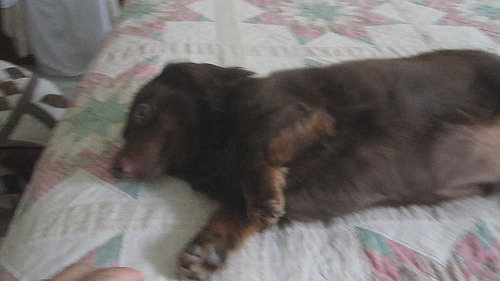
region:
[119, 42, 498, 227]
dog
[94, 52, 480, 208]
brown dog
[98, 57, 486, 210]
brown dog lying on side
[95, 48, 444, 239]
brown dog lying on side on bed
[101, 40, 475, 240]
brown dog lying on bed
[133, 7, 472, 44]
multi colored bed spread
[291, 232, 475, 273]
multi colored bed spread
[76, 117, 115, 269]
multi colored bed spread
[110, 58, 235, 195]
brown head of dog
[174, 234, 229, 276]
brown paw of dog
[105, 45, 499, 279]
Brown dog sleeping on bed.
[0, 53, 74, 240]
Quilt lying on bedroom floor.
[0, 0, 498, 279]
White quilt on bed.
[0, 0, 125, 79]
White tablecloth covering nightstand.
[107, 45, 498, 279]
Brown shorthaired dog lying on top of bed.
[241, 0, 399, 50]
A star shaped pattern on the white quilt.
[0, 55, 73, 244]
A red, white, and blue quilt lying on the floor.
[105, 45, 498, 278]
A brown dog.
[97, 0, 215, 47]
A pattern on the white quilt.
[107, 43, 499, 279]
Brown dog.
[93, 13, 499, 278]
a dog sleeping on a bed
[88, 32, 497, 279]
a dog is lying on his side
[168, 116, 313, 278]
front legs of dog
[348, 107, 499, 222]
belly of dog if light brown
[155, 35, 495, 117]
body of dog is color dark brown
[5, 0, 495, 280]
a quilt cover a bed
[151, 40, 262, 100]
ear of dog is long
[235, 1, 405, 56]
quilt has star decorations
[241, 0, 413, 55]
star is red, yellow and green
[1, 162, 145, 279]
a rhombus on a quilt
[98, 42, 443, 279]
Dog taking a nap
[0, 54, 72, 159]
Blanket on the floor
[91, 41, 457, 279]
Dog laying in his master's bed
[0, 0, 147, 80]
Bottom of a woman's dress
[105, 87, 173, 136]
The dog's eyes are wide open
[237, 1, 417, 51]
Beautiful comforter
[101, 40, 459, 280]
The dog is relaxing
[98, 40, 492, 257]
The dog has a long brown coat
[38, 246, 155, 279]
The owner's hand seems to be in the bottom of the picture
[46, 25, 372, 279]
The bed was made perfectly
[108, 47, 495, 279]
dog laying on bed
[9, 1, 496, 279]
a quilt on a bed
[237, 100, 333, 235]
left leg of a dog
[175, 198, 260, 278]
right leg of dog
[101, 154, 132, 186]
nose of a dog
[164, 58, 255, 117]
left ear of a dog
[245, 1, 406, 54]
star pattern on a quilt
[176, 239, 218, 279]
bottom of dog's paw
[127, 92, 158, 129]
left eye of reclining dog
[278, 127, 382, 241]
chest area of reclining dog